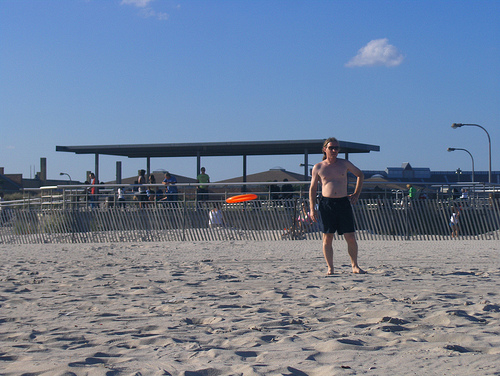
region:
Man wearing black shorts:
[303, 188, 360, 241]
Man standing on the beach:
[299, 130, 374, 276]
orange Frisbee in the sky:
[215, 180, 263, 216]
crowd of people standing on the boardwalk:
[72, 154, 212, 199]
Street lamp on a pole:
[448, 115, 473, 134]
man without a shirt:
[303, 144, 361, 201]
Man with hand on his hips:
[338, 178, 372, 203]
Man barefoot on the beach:
[318, 253, 383, 285]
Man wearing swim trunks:
[314, 188, 364, 243]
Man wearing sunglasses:
[320, 142, 342, 159]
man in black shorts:
[315, 195, 362, 232]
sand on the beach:
[297, 271, 469, 373]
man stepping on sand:
[297, 256, 379, 286]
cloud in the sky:
[345, 34, 412, 71]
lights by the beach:
[434, 115, 495, 197]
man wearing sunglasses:
[325, 142, 340, 155]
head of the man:
[312, 131, 343, 161]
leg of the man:
[315, 225, 342, 276]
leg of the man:
[335, 228, 367, 277]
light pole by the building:
[52, 170, 74, 182]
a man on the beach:
[175, 93, 482, 278]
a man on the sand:
[283, 108, 406, 356]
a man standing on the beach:
[199, 68, 499, 375]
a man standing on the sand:
[243, 126, 472, 372]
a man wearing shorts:
[252, 73, 489, 342]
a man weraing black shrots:
[273, 70, 465, 359]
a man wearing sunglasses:
[292, 101, 419, 307]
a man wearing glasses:
[292, 88, 438, 326]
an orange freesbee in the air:
[169, 159, 344, 304]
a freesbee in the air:
[211, 166, 288, 282]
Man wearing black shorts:
[303, 132, 375, 274]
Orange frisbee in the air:
[215, 183, 262, 211]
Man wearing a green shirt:
[401, 181, 423, 212]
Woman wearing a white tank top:
[200, 197, 228, 232]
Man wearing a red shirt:
[82, 168, 102, 203]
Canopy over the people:
[50, 130, 385, 207]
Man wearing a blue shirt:
[153, 169, 181, 200]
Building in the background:
[375, 151, 441, 201]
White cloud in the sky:
[333, 24, 413, 81]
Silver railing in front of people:
[36, 178, 332, 213]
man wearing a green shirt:
[197, 175, 212, 190]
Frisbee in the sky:
[216, 188, 264, 207]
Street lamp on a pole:
[446, 113, 498, 198]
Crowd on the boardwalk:
[81, 158, 217, 199]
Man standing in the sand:
[295, 130, 387, 282]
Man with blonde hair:
[317, 132, 345, 162]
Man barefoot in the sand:
[311, 258, 371, 276]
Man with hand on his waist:
[298, 187, 372, 232]